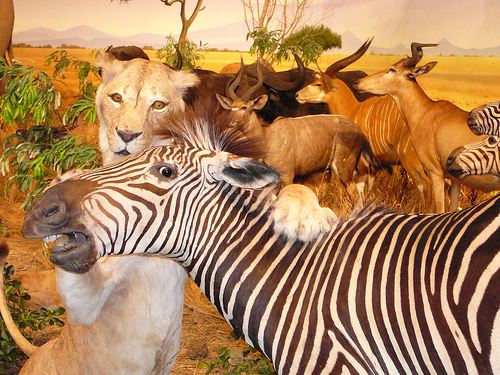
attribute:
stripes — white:
[366, 98, 416, 163]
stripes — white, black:
[184, 195, 498, 374]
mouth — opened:
[28, 217, 68, 255]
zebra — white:
[24, 107, 499, 369]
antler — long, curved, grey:
[244, 56, 267, 98]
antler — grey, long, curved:
[224, 55, 245, 99]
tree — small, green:
[277, 24, 342, 67]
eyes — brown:
[77, 73, 162, 130]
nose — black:
[19, 192, 74, 234]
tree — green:
[276, 20, 349, 76]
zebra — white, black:
[15, 158, 495, 373]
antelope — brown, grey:
[216, 57, 361, 191]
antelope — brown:
[353, 39, 497, 211]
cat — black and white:
[21, 48, 198, 371]